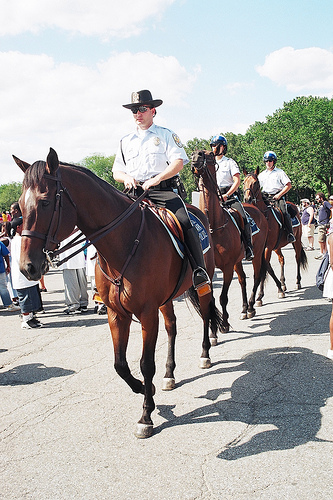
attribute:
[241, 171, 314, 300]
horse — rear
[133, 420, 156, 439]
hoof — gray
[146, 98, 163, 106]
brim — wide, black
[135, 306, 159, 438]
leg — the   right ,  horse's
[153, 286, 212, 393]
back legs —  horse's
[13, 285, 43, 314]
shorts — blue , jean 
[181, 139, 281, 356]
horse — middle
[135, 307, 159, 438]
left leg —  horse's, the left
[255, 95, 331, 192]
tree — vibrant green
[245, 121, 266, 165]
tree — vibrant green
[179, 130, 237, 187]
tree — vibrant green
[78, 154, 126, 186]
tree — vibrant green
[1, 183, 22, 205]
tree — vibrant green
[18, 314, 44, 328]
sneakers — black, white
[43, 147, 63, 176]
ear — black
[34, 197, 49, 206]
eye —  horse's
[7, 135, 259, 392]
horse —  The front left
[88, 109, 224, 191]
shirt — white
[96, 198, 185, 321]
strap — black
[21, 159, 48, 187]
hair — black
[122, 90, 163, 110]
hat — black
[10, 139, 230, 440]
horse — forefront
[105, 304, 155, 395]
leg —  horse's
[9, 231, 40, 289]
t-shirt — white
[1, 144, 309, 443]
horses —  many